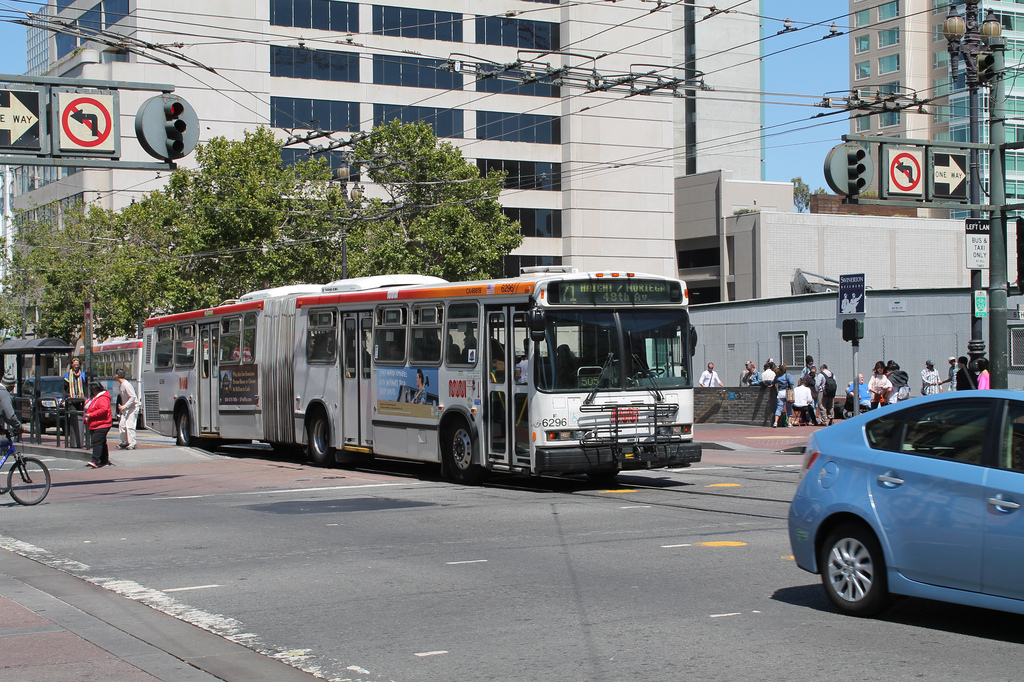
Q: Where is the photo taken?
A: At an intersection.